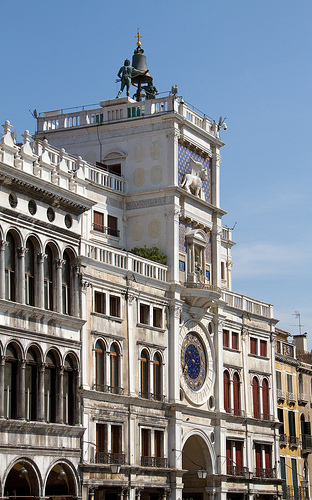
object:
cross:
[134, 30, 145, 46]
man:
[115, 60, 135, 96]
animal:
[181, 158, 209, 203]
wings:
[190, 159, 204, 172]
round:
[178, 318, 215, 407]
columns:
[167, 307, 180, 403]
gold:
[193, 336, 201, 343]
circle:
[182, 334, 208, 390]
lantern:
[198, 467, 207, 480]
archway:
[178, 419, 218, 474]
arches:
[3, 453, 80, 498]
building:
[0, 30, 312, 498]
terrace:
[182, 225, 215, 288]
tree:
[130, 246, 165, 261]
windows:
[223, 330, 277, 477]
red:
[233, 334, 237, 348]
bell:
[132, 31, 148, 77]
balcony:
[96, 383, 126, 394]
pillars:
[109, 347, 116, 390]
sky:
[0, 0, 310, 354]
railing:
[141, 453, 174, 466]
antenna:
[293, 310, 305, 336]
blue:
[0, 42, 71, 98]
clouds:
[236, 230, 302, 280]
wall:
[28, 113, 171, 186]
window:
[96, 294, 106, 315]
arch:
[182, 428, 217, 472]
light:
[110, 463, 122, 474]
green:
[130, 244, 167, 258]